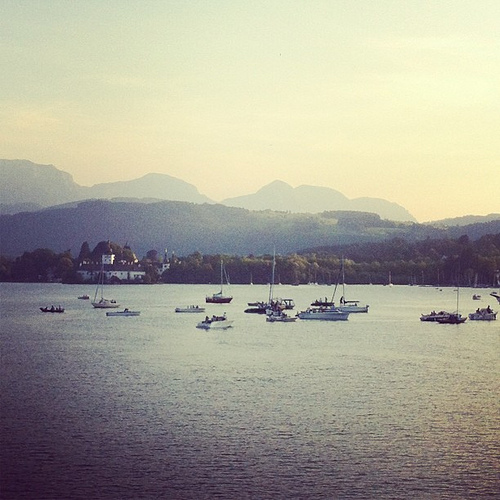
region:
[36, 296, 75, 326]
this is a boat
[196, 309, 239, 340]
this is a boat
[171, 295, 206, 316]
this is a boat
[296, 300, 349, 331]
this is a boat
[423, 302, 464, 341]
this is a boat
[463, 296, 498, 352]
this is a boat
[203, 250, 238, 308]
this is a boat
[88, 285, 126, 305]
this is a boat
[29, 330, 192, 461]
this is a body of water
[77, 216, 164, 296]
this is a building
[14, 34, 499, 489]
a scene at a ocean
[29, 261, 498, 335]
a group of boats on top of water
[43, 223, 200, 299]
a building in background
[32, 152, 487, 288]
some hills in the background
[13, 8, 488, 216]
a hazy sky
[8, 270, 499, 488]
a calm body of water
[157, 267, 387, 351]
boats in the water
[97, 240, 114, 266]
steeple on the white house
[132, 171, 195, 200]
hazy gray blue mountain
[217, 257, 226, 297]
pole with lines on the boat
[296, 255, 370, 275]
green trees in back of the boats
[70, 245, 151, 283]
white house with black roof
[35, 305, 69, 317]
people in a canoe in the water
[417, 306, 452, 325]
people in the boat in the water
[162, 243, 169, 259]
steeples on the houses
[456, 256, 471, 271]
green leaves on the tree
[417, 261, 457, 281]
green leaves on the tree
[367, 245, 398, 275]
green leaves on the tree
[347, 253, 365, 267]
green leaves on the tree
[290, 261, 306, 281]
green leaves on the tree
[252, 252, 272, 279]
green leaves on the tree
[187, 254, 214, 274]
green leaves on the tree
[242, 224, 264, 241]
green leaves on the tree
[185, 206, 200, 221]
green leaves on the tree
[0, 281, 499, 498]
the large body of water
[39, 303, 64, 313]
the people on the boat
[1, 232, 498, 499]
the trees next to the water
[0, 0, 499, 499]
the sky above the boats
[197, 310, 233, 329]
the boat is white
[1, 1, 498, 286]
the sky above the mountains and trees